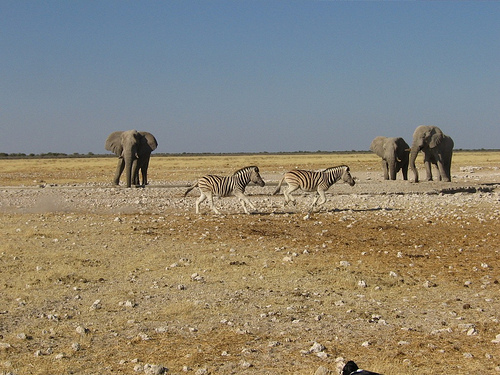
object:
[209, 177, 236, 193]
stripes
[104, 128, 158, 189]
elephant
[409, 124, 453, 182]
elephants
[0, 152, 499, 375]
desert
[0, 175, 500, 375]
rocks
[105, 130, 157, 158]
ears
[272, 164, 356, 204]
zebra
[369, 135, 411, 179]
elephant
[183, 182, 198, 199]
tail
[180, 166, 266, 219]
zebra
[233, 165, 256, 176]
mane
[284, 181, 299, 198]
legs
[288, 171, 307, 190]
dirt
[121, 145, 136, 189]
trunk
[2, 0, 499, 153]
sky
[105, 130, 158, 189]
head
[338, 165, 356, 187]
head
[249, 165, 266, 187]
head